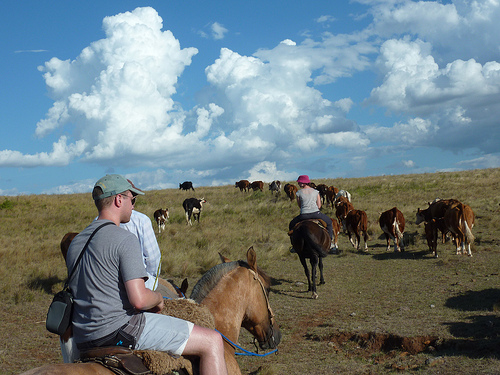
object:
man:
[48, 173, 229, 375]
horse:
[19, 245, 283, 375]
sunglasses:
[117, 195, 137, 205]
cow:
[292, 209, 339, 300]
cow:
[341, 209, 370, 252]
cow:
[377, 205, 406, 255]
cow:
[433, 202, 476, 257]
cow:
[181, 197, 207, 226]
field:
[4, 173, 497, 373]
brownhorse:
[23, 244, 281, 374]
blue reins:
[213, 328, 278, 357]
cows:
[412, 199, 456, 243]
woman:
[287, 175, 335, 251]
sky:
[7, 0, 499, 167]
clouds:
[31, 0, 197, 146]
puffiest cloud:
[223, 62, 306, 138]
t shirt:
[58, 221, 147, 343]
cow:
[154, 208, 170, 234]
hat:
[88, 171, 148, 196]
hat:
[294, 174, 310, 184]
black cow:
[178, 180, 195, 192]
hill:
[18, 168, 478, 205]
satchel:
[40, 220, 120, 340]